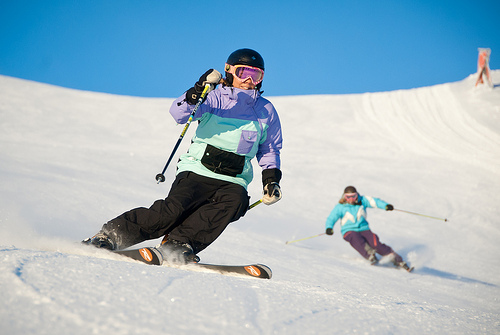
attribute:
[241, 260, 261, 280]
logo — orange and white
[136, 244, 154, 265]
logo — orange and white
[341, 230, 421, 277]
pants — purple, orange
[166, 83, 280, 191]
jacket — purple, blue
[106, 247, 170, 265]
ski — black, orange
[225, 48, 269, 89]
helmet — black 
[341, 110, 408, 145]
landscape — snowy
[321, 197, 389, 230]
jacket — blue and white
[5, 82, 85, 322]
snow — white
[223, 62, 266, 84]
goggles — pink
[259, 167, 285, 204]
gloves — black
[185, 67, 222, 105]
gloves — black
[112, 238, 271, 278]
skis — black, white , orange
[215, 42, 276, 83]
helmet — black 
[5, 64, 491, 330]
snow — thick 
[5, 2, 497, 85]
sky — clear